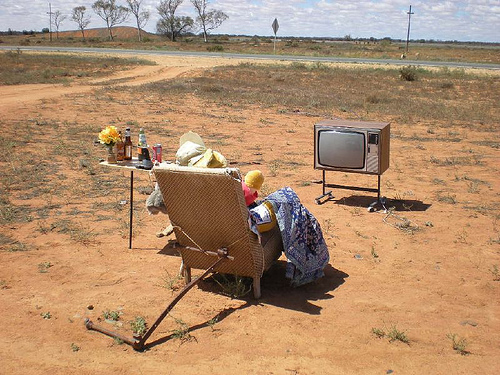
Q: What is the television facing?
A: Chair.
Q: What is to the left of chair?
A: Beverage stand.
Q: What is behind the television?
A: Road.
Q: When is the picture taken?
A: Daytime.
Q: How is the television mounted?
A: On a stand.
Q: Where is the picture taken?
A: Beside street.